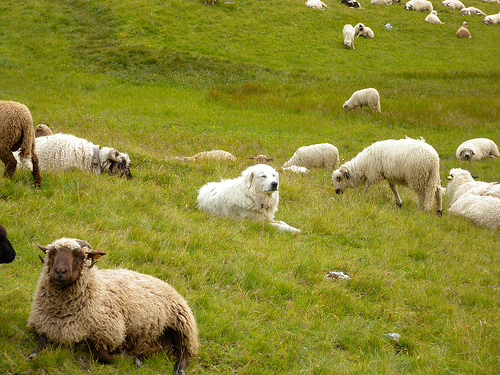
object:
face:
[48, 238, 90, 284]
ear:
[337, 166, 349, 180]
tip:
[17, 153, 34, 170]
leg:
[173, 323, 198, 375]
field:
[2, 0, 499, 374]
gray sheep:
[283, 142, 341, 173]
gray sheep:
[341, 87, 381, 116]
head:
[35, 236, 107, 291]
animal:
[456, 19, 472, 38]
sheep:
[1, 99, 41, 188]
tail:
[13, 104, 33, 173]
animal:
[194, 162, 300, 231]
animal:
[24, 235, 200, 374]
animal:
[330, 133, 442, 215]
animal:
[341, 24, 357, 51]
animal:
[281, 142, 341, 174]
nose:
[271, 180, 279, 188]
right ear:
[240, 165, 253, 190]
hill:
[0, 1, 499, 85]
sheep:
[12, 129, 133, 180]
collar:
[91, 142, 102, 171]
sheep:
[339, 0, 363, 10]